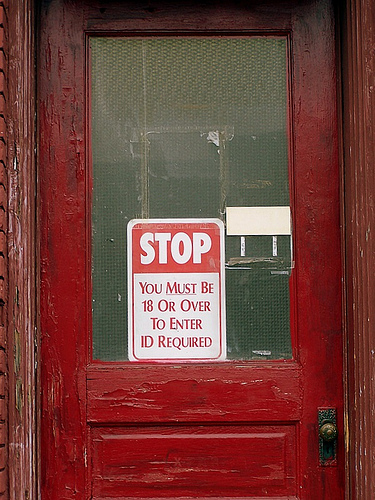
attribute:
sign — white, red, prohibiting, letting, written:
[124, 214, 230, 363]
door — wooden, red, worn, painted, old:
[38, 0, 347, 499]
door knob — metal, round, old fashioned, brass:
[311, 407, 345, 467]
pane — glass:
[84, 35, 300, 362]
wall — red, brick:
[0, 1, 12, 499]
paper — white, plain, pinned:
[220, 198, 293, 239]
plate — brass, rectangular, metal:
[320, 404, 333, 464]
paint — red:
[324, 457, 337, 469]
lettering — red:
[135, 274, 212, 358]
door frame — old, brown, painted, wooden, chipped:
[9, 2, 45, 496]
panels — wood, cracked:
[69, 365, 310, 495]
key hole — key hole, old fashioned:
[323, 443, 332, 456]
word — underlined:
[161, 280, 200, 297]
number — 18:
[139, 298, 155, 314]